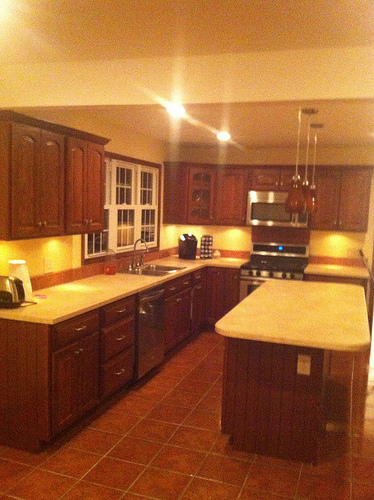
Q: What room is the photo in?
A: It is at the kitchen.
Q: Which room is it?
A: It is a kitchen.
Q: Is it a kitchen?
A: Yes, it is a kitchen.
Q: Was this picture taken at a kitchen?
A: Yes, it was taken in a kitchen.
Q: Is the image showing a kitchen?
A: Yes, it is showing a kitchen.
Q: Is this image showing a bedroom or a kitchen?
A: It is showing a kitchen.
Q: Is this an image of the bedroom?
A: No, the picture is showing the kitchen.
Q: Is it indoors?
A: Yes, it is indoors.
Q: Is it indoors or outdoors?
A: It is indoors.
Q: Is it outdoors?
A: No, it is indoors.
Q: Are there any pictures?
A: No, there are no pictures.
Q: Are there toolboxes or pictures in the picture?
A: No, there are no pictures or toolboxes.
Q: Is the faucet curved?
A: Yes, the faucet is curved.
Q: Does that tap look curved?
A: Yes, the tap is curved.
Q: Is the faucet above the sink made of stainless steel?
A: Yes, the faucet is made of stainless steel.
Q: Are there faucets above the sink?
A: Yes, there is a faucet above the sink.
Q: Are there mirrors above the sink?
A: No, there is a faucet above the sink.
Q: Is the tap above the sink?
A: Yes, the tap is above the sink.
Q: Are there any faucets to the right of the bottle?
A: Yes, there is a faucet to the right of the bottle.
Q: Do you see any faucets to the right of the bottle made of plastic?
A: Yes, there is a faucet to the right of the bottle.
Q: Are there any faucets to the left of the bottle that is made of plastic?
A: No, the faucet is to the right of the bottle.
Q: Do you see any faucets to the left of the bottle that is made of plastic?
A: No, the faucet is to the right of the bottle.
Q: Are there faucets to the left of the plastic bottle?
A: No, the faucet is to the right of the bottle.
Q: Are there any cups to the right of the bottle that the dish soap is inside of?
A: No, there is a faucet to the right of the bottle.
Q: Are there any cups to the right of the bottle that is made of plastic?
A: No, there is a faucet to the right of the bottle.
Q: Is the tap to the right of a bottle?
A: Yes, the tap is to the right of a bottle.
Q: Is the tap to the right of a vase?
A: No, the tap is to the right of a bottle.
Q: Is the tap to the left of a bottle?
A: No, the tap is to the right of a bottle.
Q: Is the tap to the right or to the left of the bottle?
A: The tap is to the right of the bottle.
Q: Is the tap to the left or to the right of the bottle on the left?
A: The tap is to the right of the bottle.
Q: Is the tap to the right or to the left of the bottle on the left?
A: The tap is to the right of the bottle.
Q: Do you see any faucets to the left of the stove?
A: Yes, there is a faucet to the left of the stove.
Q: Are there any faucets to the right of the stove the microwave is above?
A: No, the faucet is to the left of the stove.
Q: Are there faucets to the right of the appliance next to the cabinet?
A: No, the faucet is to the left of the stove.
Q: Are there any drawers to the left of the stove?
A: No, there is a faucet to the left of the stove.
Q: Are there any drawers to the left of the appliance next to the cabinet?
A: No, there is a faucet to the left of the stove.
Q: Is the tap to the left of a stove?
A: Yes, the tap is to the left of a stove.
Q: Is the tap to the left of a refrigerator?
A: No, the tap is to the left of a stove.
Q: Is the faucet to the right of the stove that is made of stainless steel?
A: No, the faucet is to the left of the stove.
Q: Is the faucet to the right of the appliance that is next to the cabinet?
A: No, the faucet is to the left of the stove.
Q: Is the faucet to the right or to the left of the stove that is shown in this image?
A: The faucet is to the left of the stove.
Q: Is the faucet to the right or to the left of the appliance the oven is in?
A: The faucet is to the left of the stove.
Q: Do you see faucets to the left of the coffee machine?
A: Yes, there is a faucet to the left of the coffee machine.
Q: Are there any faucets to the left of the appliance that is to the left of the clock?
A: Yes, there is a faucet to the left of the coffee machine.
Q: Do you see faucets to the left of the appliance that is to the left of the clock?
A: Yes, there is a faucet to the left of the coffee machine.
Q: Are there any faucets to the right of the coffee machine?
A: No, the faucet is to the left of the coffee machine.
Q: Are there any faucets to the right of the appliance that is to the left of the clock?
A: No, the faucet is to the left of the coffee machine.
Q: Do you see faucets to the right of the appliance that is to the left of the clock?
A: No, the faucet is to the left of the coffee machine.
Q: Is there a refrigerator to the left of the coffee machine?
A: No, there is a faucet to the left of the coffee machine.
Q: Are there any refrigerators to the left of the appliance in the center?
A: No, there is a faucet to the left of the coffee machine.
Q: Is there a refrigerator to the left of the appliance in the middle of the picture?
A: No, there is a faucet to the left of the coffee machine.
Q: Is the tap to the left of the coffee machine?
A: Yes, the tap is to the left of the coffee machine.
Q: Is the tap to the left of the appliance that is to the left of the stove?
A: Yes, the tap is to the left of the coffee machine.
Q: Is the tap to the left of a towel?
A: No, the tap is to the left of the coffee machine.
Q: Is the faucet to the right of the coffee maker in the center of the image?
A: No, the faucet is to the left of the coffee maker.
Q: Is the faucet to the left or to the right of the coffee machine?
A: The faucet is to the left of the coffee machine.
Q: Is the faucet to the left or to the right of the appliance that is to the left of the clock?
A: The faucet is to the left of the coffee machine.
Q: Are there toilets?
A: No, there are no toilets.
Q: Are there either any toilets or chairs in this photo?
A: No, there are no toilets or chairs.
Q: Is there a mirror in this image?
A: No, there are no mirrors.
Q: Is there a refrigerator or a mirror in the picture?
A: No, there are no mirrors or refrigerators.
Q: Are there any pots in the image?
A: No, there are no pots.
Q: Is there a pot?
A: No, there are no pots.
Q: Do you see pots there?
A: No, there are no pots.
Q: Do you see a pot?
A: No, there are no pots.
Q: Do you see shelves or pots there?
A: No, there are no pots or shelves.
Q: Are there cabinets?
A: Yes, there is a cabinet.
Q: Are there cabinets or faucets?
A: Yes, there is a cabinet.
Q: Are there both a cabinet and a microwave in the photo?
A: Yes, there are both a cabinet and a microwave.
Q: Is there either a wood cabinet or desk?
A: Yes, there is a wood cabinet.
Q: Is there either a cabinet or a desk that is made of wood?
A: Yes, the cabinet is made of wood.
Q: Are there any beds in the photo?
A: No, there are no beds.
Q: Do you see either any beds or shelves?
A: No, there are no beds or shelves.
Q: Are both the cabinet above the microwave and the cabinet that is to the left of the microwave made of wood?
A: Yes, both the cabinet and the cabinet are made of wood.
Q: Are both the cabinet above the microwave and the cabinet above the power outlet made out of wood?
A: Yes, both the cabinet and the cabinet are made of wood.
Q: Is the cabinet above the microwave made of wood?
A: Yes, the cabinet is made of wood.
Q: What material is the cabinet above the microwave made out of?
A: The cabinet is made of wood.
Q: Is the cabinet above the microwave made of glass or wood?
A: The cabinet is made of wood.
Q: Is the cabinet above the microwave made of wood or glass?
A: The cabinet is made of wood.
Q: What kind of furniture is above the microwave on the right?
A: The piece of furniture is a cabinet.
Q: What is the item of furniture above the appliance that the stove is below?
A: The piece of furniture is a cabinet.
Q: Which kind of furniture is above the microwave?
A: The piece of furniture is a cabinet.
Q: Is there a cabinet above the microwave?
A: Yes, there is a cabinet above the microwave.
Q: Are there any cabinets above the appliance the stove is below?
A: Yes, there is a cabinet above the microwave.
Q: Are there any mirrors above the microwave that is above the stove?
A: No, there is a cabinet above the microwave.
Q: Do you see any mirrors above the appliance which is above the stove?
A: No, there is a cabinet above the microwave.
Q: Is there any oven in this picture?
A: Yes, there is an oven.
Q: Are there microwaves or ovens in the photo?
A: Yes, there is an oven.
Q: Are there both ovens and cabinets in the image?
A: Yes, there are both an oven and a cabinet.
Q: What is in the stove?
A: The oven is in the stove.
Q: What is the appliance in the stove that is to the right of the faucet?
A: The appliance is an oven.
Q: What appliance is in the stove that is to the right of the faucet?
A: The appliance is an oven.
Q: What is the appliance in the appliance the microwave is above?
A: The appliance is an oven.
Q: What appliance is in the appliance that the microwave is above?
A: The appliance is an oven.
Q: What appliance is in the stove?
A: The appliance is an oven.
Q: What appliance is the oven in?
A: The oven is in the stove.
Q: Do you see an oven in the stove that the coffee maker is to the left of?
A: Yes, there is an oven in the stove.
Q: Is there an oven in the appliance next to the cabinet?
A: Yes, there is an oven in the stove.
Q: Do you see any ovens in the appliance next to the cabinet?
A: Yes, there is an oven in the stove.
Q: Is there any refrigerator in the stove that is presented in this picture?
A: No, there is an oven in the stove.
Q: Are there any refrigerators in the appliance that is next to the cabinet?
A: No, there is an oven in the stove.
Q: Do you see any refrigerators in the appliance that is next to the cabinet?
A: No, there is an oven in the stove.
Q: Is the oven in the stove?
A: Yes, the oven is in the stove.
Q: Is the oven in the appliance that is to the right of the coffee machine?
A: Yes, the oven is in the stove.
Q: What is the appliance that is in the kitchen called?
A: The appliance is an oven.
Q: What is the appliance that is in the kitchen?
A: The appliance is an oven.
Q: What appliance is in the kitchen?
A: The appliance is an oven.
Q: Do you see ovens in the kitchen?
A: Yes, there is an oven in the kitchen.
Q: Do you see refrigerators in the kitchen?
A: No, there is an oven in the kitchen.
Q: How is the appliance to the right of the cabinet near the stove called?
A: The appliance is an oven.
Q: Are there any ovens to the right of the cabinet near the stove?
A: Yes, there is an oven to the right of the cabinet.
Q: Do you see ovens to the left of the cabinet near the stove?
A: No, the oven is to the right of the cabinet.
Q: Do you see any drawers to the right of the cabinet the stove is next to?
A: No, there is an oven to the right of the cabinet.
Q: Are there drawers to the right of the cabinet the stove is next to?
A: No, there is an oven to the right of the cabinet.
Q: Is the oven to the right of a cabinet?
A: Yes, the oven is to the right of a cabinet.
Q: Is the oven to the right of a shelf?
A: No, the oven is to the right of a cabinet.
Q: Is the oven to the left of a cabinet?
A: No, the oven is to the right of a cabinet.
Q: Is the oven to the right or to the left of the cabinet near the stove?
A: The oven is to the right of the cabinet.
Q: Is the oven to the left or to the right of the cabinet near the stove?
A: The oven is to the right of the cabinet.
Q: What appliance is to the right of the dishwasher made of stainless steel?
A: The appliance is an oven.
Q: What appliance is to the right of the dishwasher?
A: The appliance is an oven.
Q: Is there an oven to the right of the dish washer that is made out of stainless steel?
A: Yes, there is an oven to the right of the dishwasher.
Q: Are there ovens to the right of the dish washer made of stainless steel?
A: Yes, there is an oven to the right of the dishwasher.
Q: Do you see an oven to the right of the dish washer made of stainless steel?
A: Yes, there is an oven to the right of the dishwasher.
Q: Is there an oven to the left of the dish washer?
A: No, the oven is to the right of the dish washer.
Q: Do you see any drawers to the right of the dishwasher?
A: No, there is an oven to the right of the dishwasher.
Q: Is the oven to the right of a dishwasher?
A: Yes, the oven is to the right of a dishwasher.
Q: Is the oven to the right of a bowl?
A: No, the oven is to the right of a dishwasher.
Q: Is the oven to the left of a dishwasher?
A: No, the oven is to the right of a dishwasher.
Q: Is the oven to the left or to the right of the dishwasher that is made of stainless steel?
A: The oven is to the right of the dishwasher.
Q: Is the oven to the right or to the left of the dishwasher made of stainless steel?
A: The oven is to the right of the dishwasher.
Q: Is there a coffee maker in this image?
A: Yes, there is a coffee maker.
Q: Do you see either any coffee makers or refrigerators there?
A: Yes, there is a coffee maker.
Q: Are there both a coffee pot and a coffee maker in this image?
A: No, there is a coffee maker but no coffee pots.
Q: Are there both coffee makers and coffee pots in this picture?
A: No, there is a coffee maker but no coffee pots.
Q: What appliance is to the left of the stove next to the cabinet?
A: The appliance is a coffee maker.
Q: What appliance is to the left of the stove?
A: The appliance is a coffee maker.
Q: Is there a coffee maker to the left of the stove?
A: Yes, there is a coffee maker to the left of the stove.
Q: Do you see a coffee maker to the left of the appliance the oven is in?
A: Yes, there is a coffee maker to the left of the stove.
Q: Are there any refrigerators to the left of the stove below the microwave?
A: No, there is a coffee maker to the left of the stove.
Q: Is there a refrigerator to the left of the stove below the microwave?
A: No, there is a coffee maker to the left of the stove.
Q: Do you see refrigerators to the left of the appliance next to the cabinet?
A: No, there is a coffee maker to the left of the stove.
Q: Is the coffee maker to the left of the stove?
A: Yes, the coffee maker is to the left of the stove.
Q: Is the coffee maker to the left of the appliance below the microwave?
A: Yes, the coffee maker is to the left of the stove.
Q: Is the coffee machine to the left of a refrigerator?
A: No, the coffee machine is to the left of the stove.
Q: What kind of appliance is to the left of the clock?
A: The appliance is a coffee maker.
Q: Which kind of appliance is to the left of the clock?
A: The appliance is a coffee maker.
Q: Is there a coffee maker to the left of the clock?
A: Yes, there is a coffee maker to the left of the clock.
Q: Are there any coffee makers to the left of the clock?
A: Yes, there is a coffee maker to the left of the clock.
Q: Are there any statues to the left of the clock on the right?
A: No, there is a coffee maker to the left of the clock.